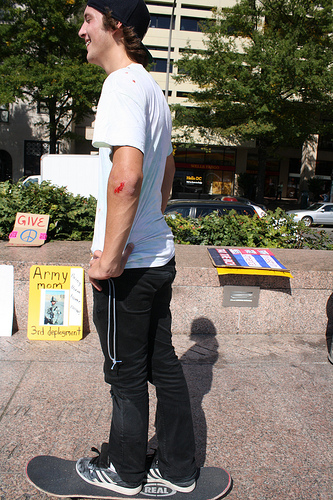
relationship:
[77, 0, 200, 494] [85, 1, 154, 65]
man wearing hat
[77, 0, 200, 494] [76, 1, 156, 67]
man has head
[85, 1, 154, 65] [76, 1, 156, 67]
hat on top of head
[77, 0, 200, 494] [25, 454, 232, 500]
man on top of skateboard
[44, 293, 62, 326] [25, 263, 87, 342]
soldier on front of sign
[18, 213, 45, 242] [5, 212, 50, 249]
give peace on front of sign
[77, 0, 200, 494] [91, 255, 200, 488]
man wearing pants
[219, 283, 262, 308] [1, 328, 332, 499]
vent on side of sidewalk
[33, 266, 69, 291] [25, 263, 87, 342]
army mom on front of sign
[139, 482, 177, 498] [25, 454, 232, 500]
logo on top of skateboard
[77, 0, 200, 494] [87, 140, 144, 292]
man has arm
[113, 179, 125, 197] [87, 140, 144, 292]
blood on back of arm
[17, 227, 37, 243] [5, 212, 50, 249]
peace sign on front of sign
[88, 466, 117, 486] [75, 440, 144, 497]
stripes on side of shoe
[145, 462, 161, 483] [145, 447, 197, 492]
stripes on side of shoe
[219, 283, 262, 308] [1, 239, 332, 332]
vent on side of ledge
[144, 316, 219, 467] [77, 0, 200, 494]
shadow of man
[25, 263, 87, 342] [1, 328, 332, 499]
sign on top of sidewalk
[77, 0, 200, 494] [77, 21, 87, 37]
man has nose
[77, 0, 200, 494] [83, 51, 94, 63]
man has chin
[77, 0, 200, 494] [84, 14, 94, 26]
man has eye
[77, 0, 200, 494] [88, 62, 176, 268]
man wearing shirt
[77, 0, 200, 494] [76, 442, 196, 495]
man wearing shoes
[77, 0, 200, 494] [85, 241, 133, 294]
man has hand